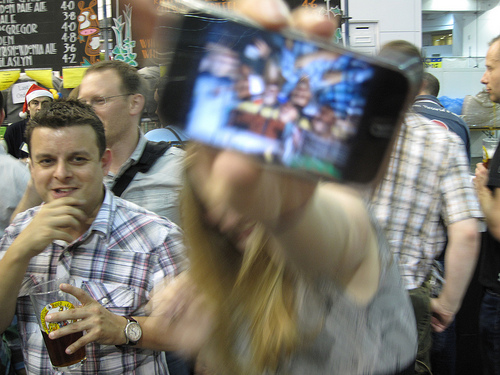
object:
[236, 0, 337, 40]
person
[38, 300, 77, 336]
decal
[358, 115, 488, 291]
back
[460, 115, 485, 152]
ground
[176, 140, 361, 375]
hair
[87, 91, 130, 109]
glasses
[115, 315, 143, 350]
watch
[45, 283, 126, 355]
hand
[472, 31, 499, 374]
guy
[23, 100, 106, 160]
hair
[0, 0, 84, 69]
beer board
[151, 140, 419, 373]
girl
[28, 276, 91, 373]
glass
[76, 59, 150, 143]
head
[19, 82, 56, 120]
hat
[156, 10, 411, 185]
cell phone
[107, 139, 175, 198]
strap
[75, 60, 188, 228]
man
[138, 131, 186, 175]
shoulder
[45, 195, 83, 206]
chin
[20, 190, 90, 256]
hand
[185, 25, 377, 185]
screen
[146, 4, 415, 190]
phone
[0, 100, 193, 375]
guy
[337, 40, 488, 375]
guy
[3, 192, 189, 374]
plaid shirt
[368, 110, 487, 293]
plaid shirt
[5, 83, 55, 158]
man